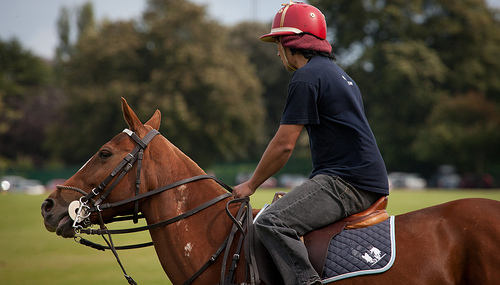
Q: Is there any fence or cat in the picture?
A: No, there are no fences or cats.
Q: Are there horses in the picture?
A: Yes, there is a horse.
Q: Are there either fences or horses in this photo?
A: Yes, there is a horse.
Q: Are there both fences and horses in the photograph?
A: No, there is a horse but no fences.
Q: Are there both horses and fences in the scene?
A: No, there is a horse but no fences.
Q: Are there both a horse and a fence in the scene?
A: No, there is a horse but no fences.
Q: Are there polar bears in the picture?
A: No, there are no polar bears.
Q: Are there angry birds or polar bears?
A: No, there are no polar bears or angry birds.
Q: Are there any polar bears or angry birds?
A: No, there are no polar bears or angry birds.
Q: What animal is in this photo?
A: The animal is a horse.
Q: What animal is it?
A: The animal is a horse.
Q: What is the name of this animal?
A: This is a horse.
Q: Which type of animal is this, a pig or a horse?
A: This is a horse.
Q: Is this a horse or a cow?
A: This is a horse.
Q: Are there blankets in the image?
A: Yes, there is a blanket.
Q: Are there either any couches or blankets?
A: Yes, there is a blanket.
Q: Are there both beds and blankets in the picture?
A: No, there is a blanket but no beds.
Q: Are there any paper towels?
A: No, there are no paper towels.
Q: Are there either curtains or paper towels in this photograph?
A: No, there are no paper towels or curtains.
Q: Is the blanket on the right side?
A: Yes, the blanket is on the right of the image.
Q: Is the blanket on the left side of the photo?
A: No, the blanket is on the right of the image.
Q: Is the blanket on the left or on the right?
A: The blanket is on the right of the image.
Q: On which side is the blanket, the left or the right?
A: The blanket is on the right of the image.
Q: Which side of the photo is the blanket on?
A: The blanket is on the right of the image.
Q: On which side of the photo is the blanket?
A: The blanket is on the right of the image.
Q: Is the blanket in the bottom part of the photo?
A: Yes, the blanket is in the bottom of the image.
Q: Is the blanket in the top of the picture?
A: No, the blanket is in the bottom of the image.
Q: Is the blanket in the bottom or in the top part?
A: The blanket is in the bottom of the image.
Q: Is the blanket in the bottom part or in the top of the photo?
A: The blanket is in the bottom of the image.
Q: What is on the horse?
A: The blanket is on the horse.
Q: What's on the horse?
A: The blanket is on the horse.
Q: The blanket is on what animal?
A: The blanket is on the horse.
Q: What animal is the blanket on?
A: The blanket is on the horse.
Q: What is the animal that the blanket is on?
A: The animal is a horse.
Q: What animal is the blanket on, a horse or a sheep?
A: The blanket is on a horse.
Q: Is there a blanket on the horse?
A: Yes, there is a blanket on the horse.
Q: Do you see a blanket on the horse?
A: Yes, there is a blanket on the horse.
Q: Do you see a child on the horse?
A: No, there is a blanket on the horse.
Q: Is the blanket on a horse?
A: Yes, the blanket is on a horse.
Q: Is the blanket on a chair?
A: No, the blanket is on a horse.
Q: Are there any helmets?
A: Yes, there is a helmet.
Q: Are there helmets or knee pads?
A: Yes, there is a helmet.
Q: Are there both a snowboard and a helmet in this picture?
A: No, there is a helmet but no snowboards.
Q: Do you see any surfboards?
A: No, there are no surfboards.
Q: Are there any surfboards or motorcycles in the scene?
A: No, there are no surfboards or motorcycles.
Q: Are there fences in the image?
A: No, there are no fences.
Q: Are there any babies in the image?
A: No, there are no babies.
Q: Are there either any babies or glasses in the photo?
A: No, there are no babies or glasses.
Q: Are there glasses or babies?
A: No, there are no babies or glasses.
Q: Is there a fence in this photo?
A: No, there are no fences.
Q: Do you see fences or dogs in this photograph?
A: No, there are no fences or dogs.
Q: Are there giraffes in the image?
A: No, there are no giraffes.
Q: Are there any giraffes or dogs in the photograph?
A: No, there are no giraffes or dogs.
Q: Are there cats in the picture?
A: No, there are no cats.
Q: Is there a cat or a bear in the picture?
A: No, there are no cats or bears.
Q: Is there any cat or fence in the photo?
A: No, there are no fences or cats.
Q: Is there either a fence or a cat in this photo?
A: No, there are no fences or cats.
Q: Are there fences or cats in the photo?
A: No, there are no fences or cats.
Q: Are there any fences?
A: No, there are no fences.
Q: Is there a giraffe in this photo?
A: No, there are no giraffes.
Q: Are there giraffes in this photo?
A: No, there are no giraffes.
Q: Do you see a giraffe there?
A: No, there are no giraffes.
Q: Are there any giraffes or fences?
A: No, there are no giraffes or fences.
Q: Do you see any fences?
A: No, there are no fences.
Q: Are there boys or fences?
A: No, there are no fences or boys.